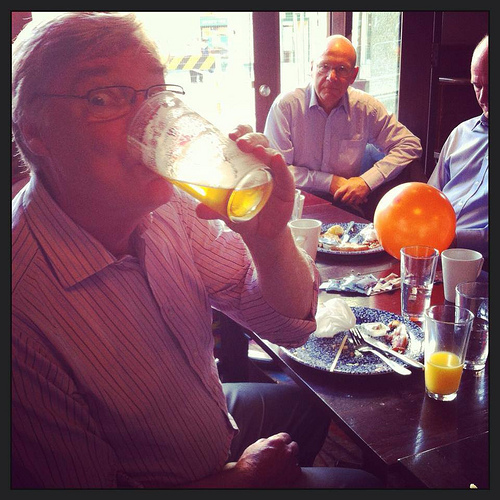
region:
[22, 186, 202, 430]
a man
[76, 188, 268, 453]
a man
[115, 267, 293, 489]
a man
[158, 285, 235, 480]
a man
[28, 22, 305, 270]
man drinking glass of beer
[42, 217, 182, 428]
striped shirt with open collar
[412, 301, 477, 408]
glass with orange juice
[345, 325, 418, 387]
two utensils on plate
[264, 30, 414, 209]
man sitting at table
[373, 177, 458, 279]
orange ball on table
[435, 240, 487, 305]
white coffee cup on table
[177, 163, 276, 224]
bottom of glass of beer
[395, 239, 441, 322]
half a glass of water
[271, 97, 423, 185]
long sleeved dress shirt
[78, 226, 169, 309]
open collar on striped shirt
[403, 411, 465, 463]
reflection on wood table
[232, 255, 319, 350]
rolled up sleeve on arm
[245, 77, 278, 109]
silver knob on door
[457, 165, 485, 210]
buttons on front of shirt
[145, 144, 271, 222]
beer in tilted glass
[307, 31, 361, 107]
man with bald head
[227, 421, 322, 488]
hand resting on leg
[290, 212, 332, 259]
white cup with handle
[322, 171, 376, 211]
hand inside another hand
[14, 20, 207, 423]
A man in a striped shirt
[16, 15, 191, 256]
A man with gray hair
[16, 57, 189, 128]
A man wearing glasses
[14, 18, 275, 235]
A man having a drink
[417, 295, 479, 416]
A glass with orange juice in it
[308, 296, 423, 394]
A plate showing the remnants of a meal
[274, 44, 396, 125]
A man with a bald head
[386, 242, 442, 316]
A glass of water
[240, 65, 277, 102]
A door knob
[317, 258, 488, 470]
A wooden table with a mess on it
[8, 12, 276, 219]
a man drinking fruit juice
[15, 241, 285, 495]
a white shirt with colorful stripes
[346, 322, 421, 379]
utensils on a plate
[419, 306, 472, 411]
a glass of orange juice on a table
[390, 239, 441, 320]
a glass of water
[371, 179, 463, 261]
an orange balloon on a table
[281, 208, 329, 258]
a white cup on a table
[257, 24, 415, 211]
a man sitting at a table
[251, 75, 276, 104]
a silver door handle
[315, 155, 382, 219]
man clasping his hands